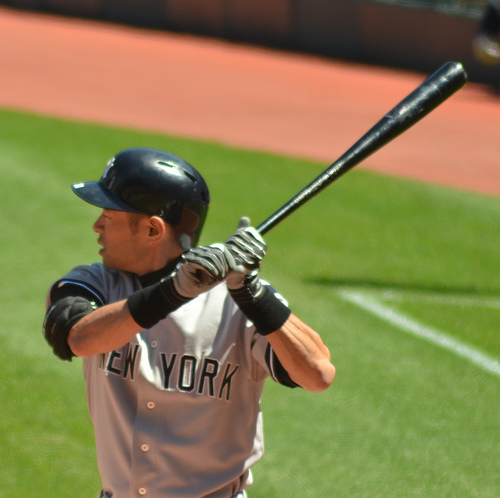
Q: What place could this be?
A: It is a field.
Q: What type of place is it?
A: It is a field.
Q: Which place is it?
A: It is a field.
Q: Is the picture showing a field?
A: Yes, it is showing a field.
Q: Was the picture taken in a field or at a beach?
A: It was taken at a field.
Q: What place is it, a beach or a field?
A: It is a field.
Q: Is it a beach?
A: No, it is a field.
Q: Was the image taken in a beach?
A: No, the picture was taken in a field.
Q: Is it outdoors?
A: Yes, it is outdoors.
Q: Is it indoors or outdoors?
A: It is outdoors.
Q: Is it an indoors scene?
A: No, it is outdoors.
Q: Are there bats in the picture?
A: Yes, there is a bat.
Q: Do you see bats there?
A: Yes, there is a bat.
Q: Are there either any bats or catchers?
A: Yes, there is a bat.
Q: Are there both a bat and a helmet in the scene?
A: Yes, there are both a bat and a helmet.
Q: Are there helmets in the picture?
A: Yes, there is a helmet.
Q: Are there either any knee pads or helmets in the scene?
A: Yes, there is a helmet.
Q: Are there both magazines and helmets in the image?
A: No, there is a helmet but no magazines.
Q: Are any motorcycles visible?
A: No, there are no motorcycles.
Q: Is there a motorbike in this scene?
A: No, there are no motorcycles.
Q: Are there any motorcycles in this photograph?
A: No, there are no motorcycles.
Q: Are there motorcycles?
A: No, there are no motorcycles.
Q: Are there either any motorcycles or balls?
A: No, there are no motorcycles or balls.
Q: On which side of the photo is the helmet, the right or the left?
A: The helmet is on the left of the image.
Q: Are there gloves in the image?
A: Yes, there are gloves.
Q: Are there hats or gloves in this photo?
A: Yes, there are gloves.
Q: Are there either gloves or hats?
A: Yes, there are gloves.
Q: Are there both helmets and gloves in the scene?
A: Yes, there are both gloves and a helmet.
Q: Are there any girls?
A: No, there are no girls.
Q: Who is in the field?
A: The player is in the field.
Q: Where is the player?
A: The player is in the field.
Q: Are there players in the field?
A: Yes, there is a player in the field.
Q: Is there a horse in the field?
A: No, there is a player in the field.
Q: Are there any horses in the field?
A: No, there is a player in the field.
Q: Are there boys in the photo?
A: No, there are no boys.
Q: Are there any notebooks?
A: No, there are no notebooks.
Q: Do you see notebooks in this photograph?
A: No, there are no notebooks.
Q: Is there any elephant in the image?
A: No, there are no elephants.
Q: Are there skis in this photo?
A: No, there are no skis.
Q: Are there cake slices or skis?
A: No, there are no skis or cake slices.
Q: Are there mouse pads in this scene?
A: No, there are no mouse pads.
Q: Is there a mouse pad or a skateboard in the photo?
A: No, there are no mouse pads or skateboards.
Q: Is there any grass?
A: Yes, there is grass.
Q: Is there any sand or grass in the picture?
A: Yes, there is grass.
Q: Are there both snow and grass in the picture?
A: No, there is grass but no snow.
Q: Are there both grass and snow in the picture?
A: No, there is grass but no snow.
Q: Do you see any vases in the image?
A: No, there are no vases.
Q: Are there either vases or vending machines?
A: No, there are no vases or vending machines.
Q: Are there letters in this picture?
A: Yes, there are letters.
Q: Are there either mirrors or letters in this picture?
A: Yes, there are letters.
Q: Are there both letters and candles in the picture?
A: No, there are letters but no candles.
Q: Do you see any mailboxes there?
A: No, there are no mailboxes.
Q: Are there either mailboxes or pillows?
A: No, there are no mailboxes or pillows.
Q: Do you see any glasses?
A: No, there are no glasses.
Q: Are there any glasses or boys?
A: No, there are no glasses or boys.